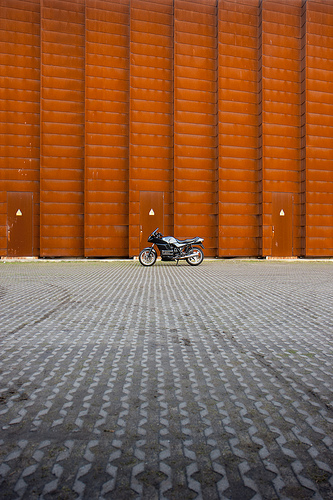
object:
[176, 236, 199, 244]
seat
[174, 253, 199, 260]
exhaust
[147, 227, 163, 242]
handle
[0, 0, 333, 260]
building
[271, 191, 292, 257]
door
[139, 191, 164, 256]
door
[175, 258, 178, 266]
peddle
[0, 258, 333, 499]
ground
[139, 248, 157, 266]
wheel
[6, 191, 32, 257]
doors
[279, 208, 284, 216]
symbol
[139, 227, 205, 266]
bike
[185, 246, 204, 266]
wheel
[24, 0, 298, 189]
walls